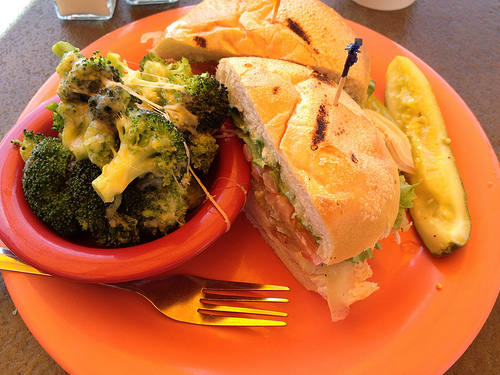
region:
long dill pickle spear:
[385, 51, 471, 259]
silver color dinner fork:
[0, 237, 295, 333]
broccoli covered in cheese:
[10, 42, 228, 247]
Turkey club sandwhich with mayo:
[158, 0, 413, 318]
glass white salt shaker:
[52, 1, 117, 21]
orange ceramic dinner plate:
[1, 2, 492, 369]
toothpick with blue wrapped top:
[330, 37, 360, 103]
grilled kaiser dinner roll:
[161, 0, 391, 262]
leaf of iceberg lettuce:
[230, 85, 410, 321]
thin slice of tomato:
[239, 140, 321, 269]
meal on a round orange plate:
[5, 8, 491, 364]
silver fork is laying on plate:
[1, 245, 287, 330]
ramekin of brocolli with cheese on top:
[5, 45, 225, 270]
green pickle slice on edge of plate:
[382, 54, 469, 255]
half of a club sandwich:
[223, 57, 405, 319]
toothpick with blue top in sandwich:
[332, 36, 364, 112]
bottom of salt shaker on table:
[50, 0, 118, 21]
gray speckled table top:
[5, 34, 46, 69]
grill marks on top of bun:
[311, 101, 330, 155]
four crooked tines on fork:
[170, 271, 292, 331]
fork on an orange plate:
[1, 241, 291, 337]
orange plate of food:
[13, 26, 494, 370]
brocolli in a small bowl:
[18, 44, 228, 235]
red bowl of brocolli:
[1, 92, 246, 282]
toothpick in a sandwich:
[334, 31, 360, 116]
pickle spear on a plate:
[381, 50, 470, 266]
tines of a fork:
[192, 268, 295, 336]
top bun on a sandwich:
[216, 50, 402, 265]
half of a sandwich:
[211, 50, 406, 322]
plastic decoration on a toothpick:
[339, 37, 364, 77]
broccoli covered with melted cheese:
[53, 52, 188, 189]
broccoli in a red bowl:
[5, 47, 247, 275]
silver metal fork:
[1, 242, 288, 333]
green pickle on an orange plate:
[382, 51, 474, 256]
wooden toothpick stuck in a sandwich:
[330, 35, 373, 130]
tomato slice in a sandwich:
[246, 162, 316, 263]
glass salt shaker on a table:
[48, 2, 118, 23]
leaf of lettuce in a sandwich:
[232, 109, 414, 260]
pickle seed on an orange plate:
[435, 281, 442, 290]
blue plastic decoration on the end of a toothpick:
[339, 33, 364, 80]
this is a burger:
[260, 86, 368, 282]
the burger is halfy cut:
[270, 118, 377, 263]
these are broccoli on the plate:
[57, 80, 211, 202]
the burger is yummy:
[282, 175, 380, 278]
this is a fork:
[190, 277, 284, 329]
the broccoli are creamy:
[72, 71, 194, 190]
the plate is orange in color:
[301, 329, 334, 369]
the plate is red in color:
[110, 246, 142, 275]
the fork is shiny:
[204, 281, 294, 333]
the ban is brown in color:
[309, 121, 342, 167]